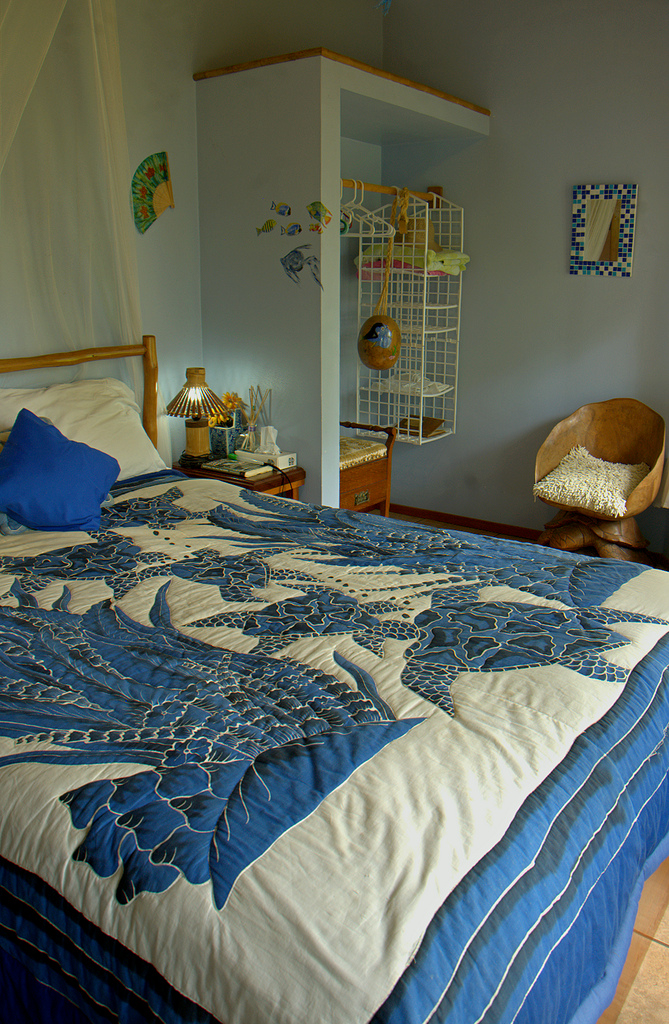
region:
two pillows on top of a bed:
[1, 375, 167, 532]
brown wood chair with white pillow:
[527, 394, 667, 566]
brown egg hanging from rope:
[354, 237, 403, 372]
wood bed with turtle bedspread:
[0, 333, 668, 1021]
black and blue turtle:
[370, 576, 667, 719]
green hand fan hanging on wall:
[127, 149, 177, 236]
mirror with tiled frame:
[564, 181, 637, 281]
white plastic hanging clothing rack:
[356, 185, 464, 443]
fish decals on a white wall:
[250, 197, 334, 294]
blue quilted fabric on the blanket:
[54, 779, 116, 830]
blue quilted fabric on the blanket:
[69, 805, 129, 875]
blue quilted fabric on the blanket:
[112, 829, 178, 904]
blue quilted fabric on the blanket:
[113, 794, 184, 845]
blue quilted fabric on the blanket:
[452, 632, 494, 674]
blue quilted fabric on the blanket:
[323, 637, 402, 725]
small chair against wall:
[521, 369, 668, 563]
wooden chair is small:
[524, 385, 667, 577]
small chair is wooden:
[520, 377, 668, 574]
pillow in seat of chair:
[540, 439, 653, 528]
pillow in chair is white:
[533, 438, 654, 530]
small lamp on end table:
[162, 354, 234, 460]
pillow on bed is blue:
[3, 397, 126, 548]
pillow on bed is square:
[2, 403, 133, 549]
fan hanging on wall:
[126, 141, 181, 231]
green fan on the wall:
[130, 141, 194, 239]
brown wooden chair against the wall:
[519, 402, 665, 537]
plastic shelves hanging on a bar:
[376, 198, 463, 438]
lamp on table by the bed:
[166, 354, 230, 470]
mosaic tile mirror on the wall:
[549, 169, 650, 290]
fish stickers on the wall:
[243, 186, 336, 300]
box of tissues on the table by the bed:
[243, 433, 297, 469]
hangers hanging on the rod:
[343, 181, 397, 255]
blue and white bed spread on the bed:
[26, 519, 606, 925]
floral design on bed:
[62, 716, 298, 915]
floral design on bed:
[54, 743, 271, 916]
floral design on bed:
[51, 742, 273, 884]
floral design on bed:
[41, 741, 264, 914]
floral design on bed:
[45, 748, 276, 933]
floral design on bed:
[53, 749, 273, 924]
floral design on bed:
[46, 740, 264, 917]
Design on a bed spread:
[232, 581, 399, 666]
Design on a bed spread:
[381, 570, 666, 712]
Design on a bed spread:
[5, 522, 147, 608]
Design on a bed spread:
[248, 566, 414, 669]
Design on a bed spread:
[171, 543, 311, 606]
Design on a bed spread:
[11, 523, 187, 612]